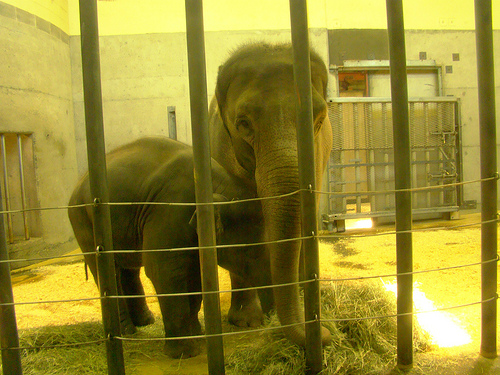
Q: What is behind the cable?
A: AN elephant's trunk.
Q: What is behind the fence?
A: A small elephant.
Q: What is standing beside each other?
A: A couple of elephants.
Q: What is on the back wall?
A: A gray gate.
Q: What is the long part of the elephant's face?
A: The trunk.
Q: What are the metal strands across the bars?
A: Wires.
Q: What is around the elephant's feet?
A: Straw.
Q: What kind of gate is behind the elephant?
A: A metal gate.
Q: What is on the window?
A: Metal bars.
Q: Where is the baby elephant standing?
A: Next to the mother.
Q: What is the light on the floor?
A: Sunlight.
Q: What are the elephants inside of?
A: A cage.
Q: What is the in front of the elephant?
A: Metal bars.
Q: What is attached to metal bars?
A: Thin wire.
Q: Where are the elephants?
A: In an enclosure.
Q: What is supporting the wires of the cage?
A: Metal bars.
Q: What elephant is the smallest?
A: The one on the left.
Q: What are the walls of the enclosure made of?
A: Cement.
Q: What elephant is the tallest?
A: The one on the right.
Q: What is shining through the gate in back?
A: Light.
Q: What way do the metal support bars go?
A: Vertically.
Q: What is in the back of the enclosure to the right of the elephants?
A: A door.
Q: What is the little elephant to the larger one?
A: Her baby.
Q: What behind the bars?
A: Elephants.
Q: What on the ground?
A: Grass.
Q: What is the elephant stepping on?
A: Straw.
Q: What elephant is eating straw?
A: The small elephant.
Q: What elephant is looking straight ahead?
A: The bigger elephant.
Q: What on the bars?
A: Wires.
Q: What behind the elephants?
A: Grey wall.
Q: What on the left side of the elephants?
A: Gate.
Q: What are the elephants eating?
A: Straw.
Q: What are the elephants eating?
A: Hay.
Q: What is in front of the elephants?
A: Bars.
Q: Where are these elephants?
A: A zoo.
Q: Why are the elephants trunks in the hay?
A: They're eating.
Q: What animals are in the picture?
A: Elephants.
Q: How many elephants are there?
A: Two.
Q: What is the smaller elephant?
A: A baby.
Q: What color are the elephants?
A: Grey.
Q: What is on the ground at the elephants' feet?
A: Hay.